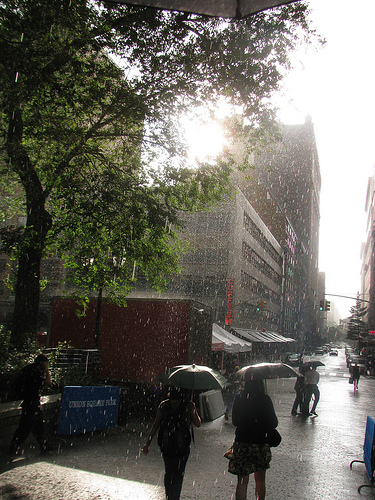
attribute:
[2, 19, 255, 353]
tree — green, leafy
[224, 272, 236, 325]
neon sign — red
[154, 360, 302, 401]
umbrellas — open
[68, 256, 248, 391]
sign — red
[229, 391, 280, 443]
coat — black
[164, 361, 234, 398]
umbrella — black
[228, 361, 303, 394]
umbrella — black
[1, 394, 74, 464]
wall — stone